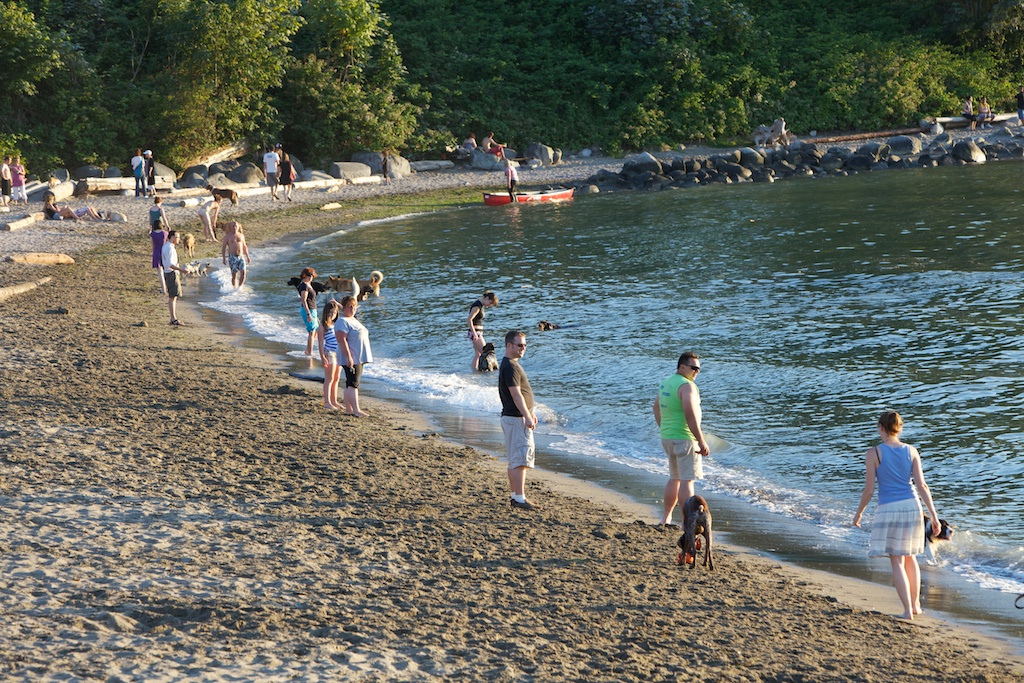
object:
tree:
[584, 1, 776, 158]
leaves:
[751, 7, 866, 103]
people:
[852, 411, 940, 621]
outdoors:
[0, 110, 970, 640]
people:
[654, 352, 711, 530]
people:
[334, 295, 373, 417]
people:
[499, 331, 538, 510]